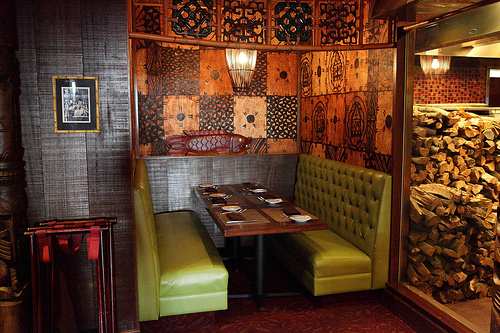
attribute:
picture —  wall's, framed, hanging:
[52, 74, 101, 134]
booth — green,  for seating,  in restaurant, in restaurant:
[136, 109, 392, 322]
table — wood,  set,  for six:
[194, 181, 327, 313]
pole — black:
[254, 235, 265, 301]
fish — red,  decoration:
[165, 129, 252, 157]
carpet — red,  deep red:
[154, 251, 435, 333]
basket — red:
[24, 216, 118, 332]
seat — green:
[136, 156, 391, 323]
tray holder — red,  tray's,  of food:
[24, 216, 116, 332]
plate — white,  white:
[289, 212, 311, 222]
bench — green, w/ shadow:
[138, 153, 393, 320]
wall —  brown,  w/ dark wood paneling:
[127, 4, 382, 256]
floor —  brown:
[75, 256, 433, 331]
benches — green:
[136, 158, 391, 324]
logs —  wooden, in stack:
[410, 104, 499, 302]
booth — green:
[127, 154, 392, 321]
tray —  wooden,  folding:
[25, 219, 117, 331]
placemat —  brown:
[238, 206, 268, 229]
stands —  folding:
[85, 222, 103, 260]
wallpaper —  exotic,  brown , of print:
[132, 4, 386, 160]